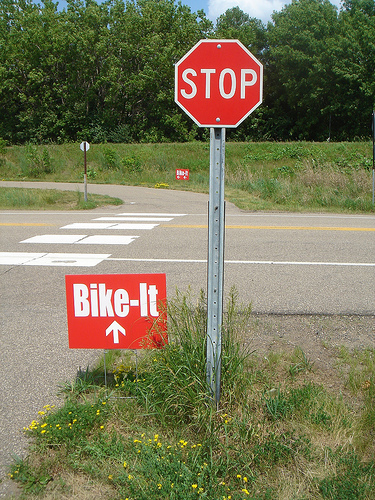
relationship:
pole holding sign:
[207, 126, 225, 401] [173, 38, 263, 129]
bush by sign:
[136, 284, 260, 477] [173, 38, 263, 129]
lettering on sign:
[181, 68, 257, 99] [169, 33, 265, 132]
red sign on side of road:
[64, 272, 168, 349] [7, 187, 372, 498]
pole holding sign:
[207, 126, 225, 401] [69, 282, 153, 339]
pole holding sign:
[207, 126, 225, 401] [77, 130, 100, 158]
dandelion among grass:
[5, 345, 257, 500] [15, 339, 372, 496]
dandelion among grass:
[35, 418, 54, 433] [15, 339, 372, 496]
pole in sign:
[80, 139, 92, 202] [79, 139, 91, 152]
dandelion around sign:
[5, 345, 257, 500] [169, 33, 265, 132]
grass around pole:
[117, 290, 284, 421] [200, 116, 231, 395]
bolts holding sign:
[206, 40, 223, 126] [162, 35, 268, 133]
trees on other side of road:
[0, 0, 372, 143] [6, 183, 368, 360]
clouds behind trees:
[201, 2, 286, 26] [254, 8, 374, 124]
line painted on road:
[28, 216, 371, 240] [4, 216, 368, 399]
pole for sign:
[207, 126, 225, 401] [174, 38, 263, 128]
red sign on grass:
[59, 270, 173, 351] [23, 293, 373, 499]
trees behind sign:
[0, 0, 375, 147] [169, 33, 265, 132]